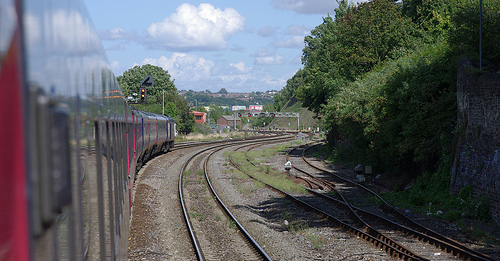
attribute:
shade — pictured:
[232, 196, 353, 231]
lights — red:
[135, 85, 148, 105]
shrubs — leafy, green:
[275, 0, 499, 224]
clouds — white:
[84, 3, 372, 98]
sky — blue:
[79, 2, 371, 114]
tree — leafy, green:
[288, 0, 462, 170]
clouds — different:
[137, 4, 243, 50]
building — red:
[192, 106, 209, 126]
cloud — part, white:
[147, 3, 244, 50]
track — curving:
[119, 110, 440, 258]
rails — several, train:
[182, 149, 319, 259]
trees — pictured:
[288, 0, 455, 187]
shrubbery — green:
[331, 34, 466, 179]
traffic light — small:
[123, 64, 172, 170]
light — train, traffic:
[137, 87, 147, 104]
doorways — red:
[119, 107, 164, 166]